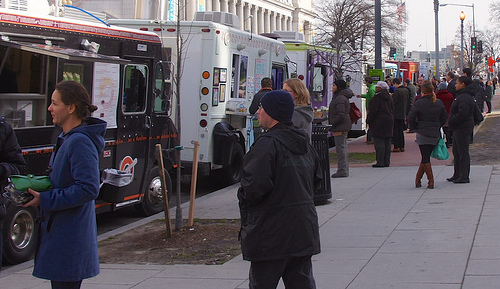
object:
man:
[237, 89, 321, 289]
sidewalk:
[0, 164, 499, 288]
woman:
[16, 80, 108, 289]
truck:
[0, 8, 179, 267]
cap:
[258, 89, 296, 125]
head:
[255, 90, 294, 126]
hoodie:
[265, 123, 311, 153]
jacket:
[236, 120, 318, 262]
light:
[200, 87, 210, 95]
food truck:
[107, 18, 296, 183]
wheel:
[142, 165, 175, 212]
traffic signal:
[470, 37, 478, 50]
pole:
[471, 5, 476, 37]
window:
[232, 50, 249, 99]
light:
[392, 57, 397, 60]